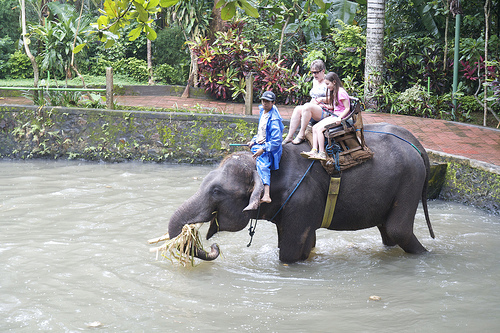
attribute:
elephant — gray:
[147, 119, 443, 268]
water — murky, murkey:
[4, 159, 500, 329]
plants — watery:
[8, 118, 63, 149]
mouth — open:
[185, 209, 234, 240]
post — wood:
[100, 68, 119, 111]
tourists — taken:
[280, 57, 357, 165]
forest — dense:
[0, 1, 500, 115]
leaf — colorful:
[461, 62, 471, 71]